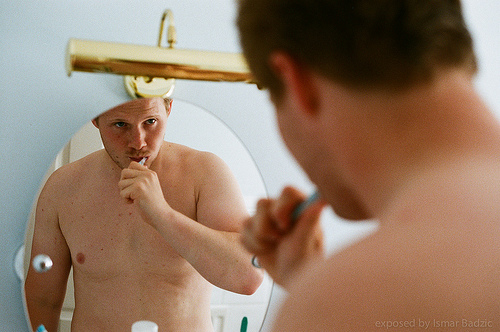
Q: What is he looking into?
A: A mirror.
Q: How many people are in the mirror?
A: 1.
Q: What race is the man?
A: Caucasian.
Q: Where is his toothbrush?
A: In his mouth.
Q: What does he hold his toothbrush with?
A: His hand.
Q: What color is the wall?
A: Light blue.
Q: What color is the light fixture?
A: Golden.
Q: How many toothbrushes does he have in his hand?
A: 1.